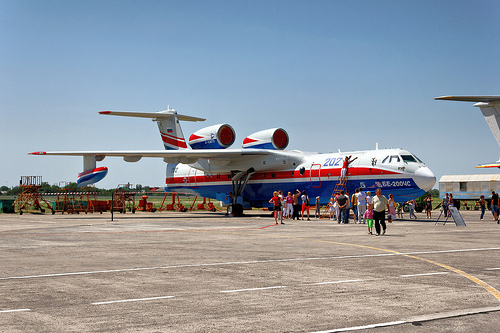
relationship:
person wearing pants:
[357, 195, 377, 224] [360, 207, 399, 239]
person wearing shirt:
[268, 182, 292, 224] [270, 197, 279, 206]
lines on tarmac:
[72, 212, 417, 332] [8, 212, 495, 331]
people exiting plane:
[267, 183, 459, 239] [29, 107, 433, 219]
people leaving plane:
[252, 154, 411, 264] [29, 107, 433, 219]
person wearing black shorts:
[364, 188, 389, 250] [272, 187, 280, 254]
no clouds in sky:
[14, 62, 496, 142] [46, 16, 446, 66]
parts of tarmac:
[5, 230, 492, 333] [8, 205, 495, 331]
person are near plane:
[369, 187, 391, 237] [29, 107, 433, 219]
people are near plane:
[337, 190, 348, 222] [29, 107, 433, 219]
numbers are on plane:
[321, 136, 348, 207] [29, 83, 479, 208]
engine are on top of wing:
[185, 120, 237, 152] [28, 145, 305, 175]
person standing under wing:
[223, 190, 244, 223] [150, 115, 242, 150]